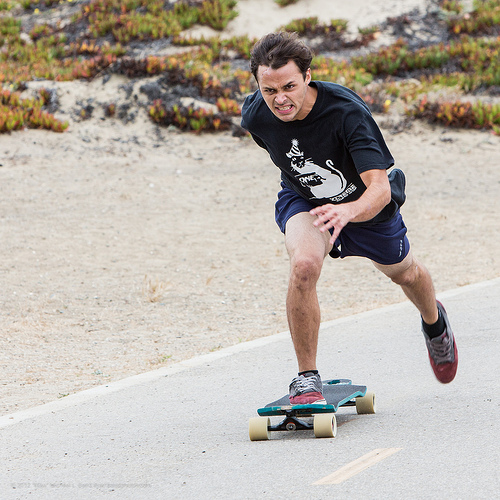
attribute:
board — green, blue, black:
[241, 371, 386, 445]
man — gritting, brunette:
[219, 24, 461, 469]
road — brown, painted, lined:
[0, 282, 499, 493]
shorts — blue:
[261, 186, 421, 281]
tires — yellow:
[262, 393, 374, 441]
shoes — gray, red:
[279, 317, 474, 407]